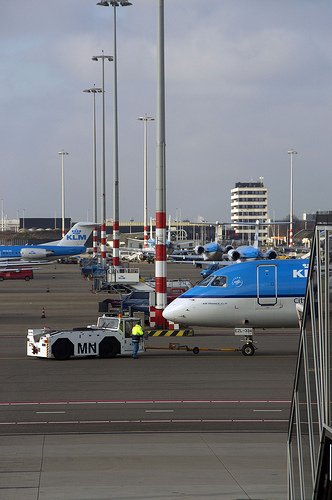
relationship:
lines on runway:
[56, 397, 190, 423] [14, 382, 302, 472]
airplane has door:
[162, 259, 309, 356] [258, 267, 277, 306]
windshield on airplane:
[205, 269, 227, 291] [162, 259, 309, 356]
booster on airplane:
[16, 236, 61, 265] [162, 259, 309, 356]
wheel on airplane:
[231, 339, 259, 357] [162, 259, 309, 356]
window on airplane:
[205, 269, 227, 291] [162, 259, 309, 356]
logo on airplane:
[66, 229, 93, 242] [162, 259, 309, 356]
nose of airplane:
[163, 286, 224, 335] [134, 247, 287, 337]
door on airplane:
[258, 267, 277, 306] [162, 259, 309, 356]